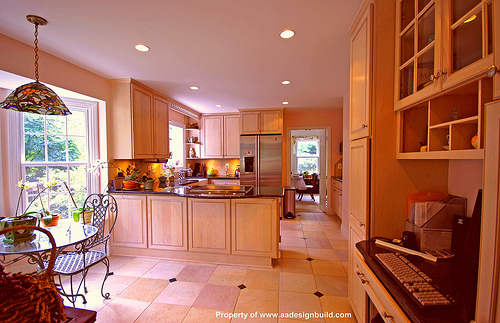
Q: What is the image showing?
A: It is showing a kitchen.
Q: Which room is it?
A: It is a kitchen.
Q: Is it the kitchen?
A: Yes, it is the kitchen.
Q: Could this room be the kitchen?
A: Yes, it is the kitchen.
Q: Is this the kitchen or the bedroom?
A: It is the kitchen.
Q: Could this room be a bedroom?
A: No, it is a kitchen.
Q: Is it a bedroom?
A: No, it is a kitchen.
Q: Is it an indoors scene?
A: Yes, it is indoors.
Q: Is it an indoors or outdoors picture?
A: It is indoors.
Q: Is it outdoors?
A: No, it is indoors.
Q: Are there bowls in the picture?
A: No, there are no bowls.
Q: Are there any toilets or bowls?
A: No, there are no bowls or toilets.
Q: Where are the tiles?
A: The tiles are on the floor.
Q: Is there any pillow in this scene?
A: No, there are no pillows.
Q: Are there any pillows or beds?
A: No, there are no pillows or beds.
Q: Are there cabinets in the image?
A: Yes, there is a cabinet.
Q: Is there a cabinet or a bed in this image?
A: Yes, there is a cabinet.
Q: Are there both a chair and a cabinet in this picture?
A: Yes, there are both a cabinet and a chair.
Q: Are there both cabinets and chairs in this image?
A: Yes, there are both a cabinet and a chair.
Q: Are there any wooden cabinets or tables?
A: Yes, there is a wood cabinet.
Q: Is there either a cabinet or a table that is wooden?
A: Yes, the cabinet is wooden.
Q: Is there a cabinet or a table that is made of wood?
A: Yes, the cabinet is made of wood.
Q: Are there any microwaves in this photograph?
A: No, there are no microwaves.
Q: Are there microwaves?
A: No, there are no microwaves.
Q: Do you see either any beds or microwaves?
A: No, there are no microwaves or beds.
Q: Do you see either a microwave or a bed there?
A: No, there are no microwaves or beds.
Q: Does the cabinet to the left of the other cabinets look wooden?
A: Yes, the cabinet is wooden.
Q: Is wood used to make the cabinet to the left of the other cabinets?
A: Yes, the cabinet is made of wood.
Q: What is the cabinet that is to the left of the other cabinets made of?
A: The cabinet is made of wood.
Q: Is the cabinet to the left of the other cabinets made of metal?
A: No, the cabinet is made of wood.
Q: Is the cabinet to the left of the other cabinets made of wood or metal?
A: The cabinet is made of wood.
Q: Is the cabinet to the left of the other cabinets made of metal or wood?
A: The cabinet is made of wood.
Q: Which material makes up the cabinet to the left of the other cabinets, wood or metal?
A: The cabinet is made of wood.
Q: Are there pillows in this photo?
A: No, there are no pillows.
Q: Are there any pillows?
A: No, there are no pillows.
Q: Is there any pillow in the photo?
A: No, there are no pillows.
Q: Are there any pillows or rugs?
A: No, there are no pillows or rugs.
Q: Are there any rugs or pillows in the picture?
A: No, there are no pillows or rugs.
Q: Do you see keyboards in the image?
A: Yes, there is a keyboard.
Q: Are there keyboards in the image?
A: Yes, there is a keyboard.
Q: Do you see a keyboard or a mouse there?
A: Yes, there is a keyboard.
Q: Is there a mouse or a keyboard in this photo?
A: Yes, there is a keyboard.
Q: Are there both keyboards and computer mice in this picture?
A: No, there is a keyboard but no computer mice.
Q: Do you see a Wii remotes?
A: No, there are no Wii controllers.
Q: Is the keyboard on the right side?
A: Yes, the keyboard is on the right of the image.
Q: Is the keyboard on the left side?
A: No, the keyboard is on the right of the image.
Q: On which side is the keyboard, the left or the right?
A: The keyboard is on the right of the image.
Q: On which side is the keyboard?
A: The keyboard is on the right of the image.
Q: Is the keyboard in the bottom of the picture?
A: Yes, the keyboard is in the bottom of the image.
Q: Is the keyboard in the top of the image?
A: No, the keyboard is in the bottom of the image.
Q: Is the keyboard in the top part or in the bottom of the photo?
A: The keyboard is in the bottom of the image.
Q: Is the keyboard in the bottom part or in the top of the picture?
A: The keyboard is in the bottom of the image.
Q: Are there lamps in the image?
A: Yes, there is a lamp.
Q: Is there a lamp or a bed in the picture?
A: Yes, there is a lamp.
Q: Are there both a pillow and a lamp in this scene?
A: No, there is a lamp but no pillows.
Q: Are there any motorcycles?
A: No, there are no motorcycles.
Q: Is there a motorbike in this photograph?
A: No, there are no motorcycles.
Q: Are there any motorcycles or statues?
A: No, there are no motorcycles or statues.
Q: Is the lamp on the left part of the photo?
A: Yes, the lamp is on the left of the image.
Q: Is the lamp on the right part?
A: No, the lamp is on the left of the image.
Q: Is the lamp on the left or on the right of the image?
A: The lamp is on the left of the image.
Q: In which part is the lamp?
A: The lamp is on the left of the image.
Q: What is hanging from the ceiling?
A: The lamp is hanging from the ceiling.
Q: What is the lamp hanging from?
A: The lamp is hanging from the ceiling.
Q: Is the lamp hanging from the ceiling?
A: Yes, the lamp is hanging from the ceiling.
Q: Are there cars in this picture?
A: No, there are no cars.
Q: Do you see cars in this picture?
A: No, there are no cars.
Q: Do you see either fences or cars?
A: No, there are no cars or fences.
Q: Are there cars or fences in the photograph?
A: No, there are no cars or fences.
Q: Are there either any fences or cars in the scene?
A: No, there are no cars or fences.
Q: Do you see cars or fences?
A: No, there are no cars or fences.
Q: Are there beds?
A: No, there are no beds.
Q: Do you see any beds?
A: No, there are no beds.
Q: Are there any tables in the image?
A: Yes, there is a table.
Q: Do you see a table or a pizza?
A: Yes, there is a table.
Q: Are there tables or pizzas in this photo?
A: Yes, there is a table.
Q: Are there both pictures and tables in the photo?
A: No, there is a table but no pictures.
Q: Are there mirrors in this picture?
A: No, there are no mirrors.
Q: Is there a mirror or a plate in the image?
A: No, there are no mirrors or plates.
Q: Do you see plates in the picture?
A: No, there are no plates.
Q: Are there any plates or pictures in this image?
A: No, there are no plates or pictures.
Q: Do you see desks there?
A: Yes, there is a desk.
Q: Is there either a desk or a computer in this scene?
A: Yes, there is a desk.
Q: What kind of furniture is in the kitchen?
A: The piece of furniture is a desk.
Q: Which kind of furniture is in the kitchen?
A: The piece of furniture is a desk.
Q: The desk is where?
A: The desk is in the kitchen.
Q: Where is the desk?
A: The desk is in the kitchen.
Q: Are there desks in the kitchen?
A: Yes, there is a desk in the kitchen.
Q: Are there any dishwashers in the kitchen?
A: No, there is a desk in the kitchen.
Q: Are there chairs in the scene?
A: Yes, there is a chair.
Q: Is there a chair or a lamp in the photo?
A: Yes, there is a chair.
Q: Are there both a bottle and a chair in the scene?
A: No, there is a chair but no bottles.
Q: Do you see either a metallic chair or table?
A: Yes, there is a metal chair.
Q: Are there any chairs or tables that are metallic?
A: Yes, the chair is metallic.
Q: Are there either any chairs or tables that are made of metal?
A: Yes, the chair is made of metal.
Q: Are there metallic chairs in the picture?
A: Yes, there is a metal chair.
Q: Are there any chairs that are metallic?
A: Yes, there is a chair that is metallic.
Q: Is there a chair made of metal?
A: Yes, there is a chair that is made of metal.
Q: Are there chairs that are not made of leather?
A: Yes, there is a chair that is made of metal.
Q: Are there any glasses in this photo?
A: No, there are no glasses.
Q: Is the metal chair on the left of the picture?
A: Yes, the chair is on the left of the image.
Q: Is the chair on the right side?
A: No, the chair is on the left of the image.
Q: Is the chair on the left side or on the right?
A: The chair is on the left of the image.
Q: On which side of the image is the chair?
A: The chair is on the left of the image.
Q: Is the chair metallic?
A: Yes, the chair is metallic.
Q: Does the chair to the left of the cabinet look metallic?
A: Yes, the chair is metallic.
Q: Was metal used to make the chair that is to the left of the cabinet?
A: Yes, the chair is made of metal.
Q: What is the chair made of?
A: The chair is made of metal.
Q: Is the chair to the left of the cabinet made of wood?
A: No, the chair is made of metal.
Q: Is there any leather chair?
A: No, there is a chair but it is made of metal.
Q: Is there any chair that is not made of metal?
A: No, there is a chair but it is made of metal.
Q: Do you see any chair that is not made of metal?
A: No, there is a chair but it is made of metal.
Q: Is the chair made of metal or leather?
A: The chair is made of metal.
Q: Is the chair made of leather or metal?
A: The chair is made of metal.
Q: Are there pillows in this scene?
A: No, there are no pillows.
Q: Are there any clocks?
A: No, there are no clocks.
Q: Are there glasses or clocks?
A: No, there are no clocks or glasses.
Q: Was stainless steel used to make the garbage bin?
A: Yes, the garbage bin is made of stainless steel.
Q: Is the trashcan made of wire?
A: No, the trashcan is made of stainless steel.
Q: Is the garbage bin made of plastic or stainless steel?
A: The garbage bin is made of stainless steel.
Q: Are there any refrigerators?
A: Yes, there is a refrigerator.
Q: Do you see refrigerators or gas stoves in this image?
A: Yes, there is a refrigerator.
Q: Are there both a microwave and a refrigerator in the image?
A: No, there is a refrigerator but no microwaves.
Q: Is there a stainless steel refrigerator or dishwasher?
A: Yes, there is a stainless steel refrigerator.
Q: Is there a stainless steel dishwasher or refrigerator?
A: Yes, there is a stainless steel refrigerator.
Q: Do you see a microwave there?
A: No, there are no microwaves.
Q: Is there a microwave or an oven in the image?
A: No, there are no microwaves or ovens.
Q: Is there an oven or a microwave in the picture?
A: No, there are no microwaves or ovens.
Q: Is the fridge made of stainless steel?
A: Yes, the fridge is made of stainless steel.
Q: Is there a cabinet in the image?
A: Yes, there is a cabinet.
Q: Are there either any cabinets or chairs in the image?
A: Yes, there is a cabinet.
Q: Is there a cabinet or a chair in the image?
A: Yes, there is a cabinet.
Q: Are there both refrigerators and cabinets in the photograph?
A: Yes, there are both a cabinet and a refrigerator.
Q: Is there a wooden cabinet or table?
A: Yes, there is a wood cabinet.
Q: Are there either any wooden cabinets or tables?
A: Yes, there is a wood cabinet.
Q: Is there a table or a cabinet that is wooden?
A: Yes, the cabinet is wooden.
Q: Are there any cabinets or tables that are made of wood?
A: Yes, the cabinet is made of wood.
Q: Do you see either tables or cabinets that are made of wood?
A: Yes, the cabinet is made of wood.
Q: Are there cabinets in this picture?
A: Yes, there is a cabinet.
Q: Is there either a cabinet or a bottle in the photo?
A: Yes, there is a cabinet.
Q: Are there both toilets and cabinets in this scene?
A: No, there is a cabinet but no toilets.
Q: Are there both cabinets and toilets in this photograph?
A: No, there is a cabinet but no toilets.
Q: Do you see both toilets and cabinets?
A: No, there is a cabinet but no toilets.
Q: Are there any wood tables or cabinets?
A: Yes, there is a wood cabinet.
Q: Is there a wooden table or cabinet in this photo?
A: Yes, there is a wood cabinet.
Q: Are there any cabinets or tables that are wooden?
A: Yes, the cabinet is wooden.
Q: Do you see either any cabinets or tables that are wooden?
A: Yes, the cabinet is wooden.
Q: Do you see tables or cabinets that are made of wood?
A: Yes, the cabinet is made of wood.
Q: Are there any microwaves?
A: No, there are no microwaves.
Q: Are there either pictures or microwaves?
A: No, there are no microwaves or pictures.